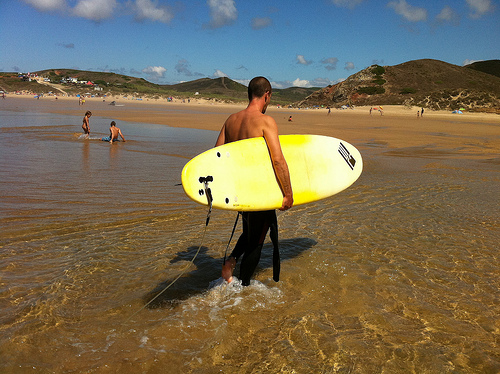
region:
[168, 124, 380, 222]
Surfboard being carried by surfer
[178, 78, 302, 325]
Surfer wading through shallow water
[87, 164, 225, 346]
Lanyard for a surfboard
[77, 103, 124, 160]
Beachgoers playing in shallow water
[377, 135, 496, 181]
Waterline at the beach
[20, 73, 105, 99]
Parking lot for beachgoers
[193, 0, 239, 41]
White clouds in the sky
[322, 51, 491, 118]
Mountain ridge adjoining beach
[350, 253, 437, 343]
Reflections of sunlight in the shallow water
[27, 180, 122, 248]
Ripples in the water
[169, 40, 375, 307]
man carrying a surf board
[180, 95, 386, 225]
yellow surfboard with writing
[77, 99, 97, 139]
little girl playing in the water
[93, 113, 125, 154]
man wearing blue shorts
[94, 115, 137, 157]
man sitting in the water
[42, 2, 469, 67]
white clouds in the sky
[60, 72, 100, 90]
house on the hill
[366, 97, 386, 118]
people playing on the beach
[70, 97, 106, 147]
little girl wearing a swimsuit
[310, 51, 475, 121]
mountains in the background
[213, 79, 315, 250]
this is a man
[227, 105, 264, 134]
the man is bare chested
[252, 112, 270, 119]
the man is light skinned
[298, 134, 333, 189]
this is a surf board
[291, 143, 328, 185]
the board is yellow in color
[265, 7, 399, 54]
this is the sky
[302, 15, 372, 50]
the sky is blue in color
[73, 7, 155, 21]
these are the clouds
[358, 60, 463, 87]
this is a mountain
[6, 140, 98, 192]
this is a water body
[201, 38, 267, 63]
this is the sky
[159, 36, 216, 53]
the sky is blue in color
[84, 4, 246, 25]
these are some clouds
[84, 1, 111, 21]
the clouds are white in color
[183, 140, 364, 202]
this is a surfboard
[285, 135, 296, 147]
the surfboard is yellow in color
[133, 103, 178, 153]
this is the beach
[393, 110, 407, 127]
the sand is brown in color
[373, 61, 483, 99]
this is a hill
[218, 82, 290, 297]
the man is walking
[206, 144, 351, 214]
the board is yellow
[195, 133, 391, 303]
the board is yellow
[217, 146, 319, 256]
the board is yellow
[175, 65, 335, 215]
the board is yellow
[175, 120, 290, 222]
the board is yellow